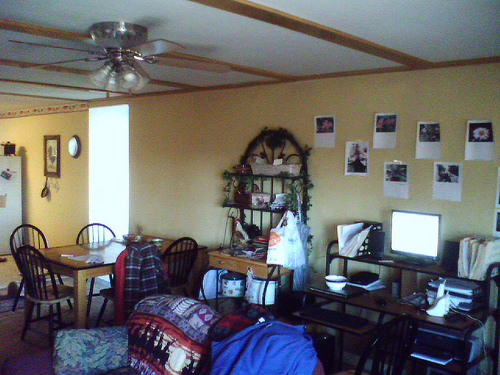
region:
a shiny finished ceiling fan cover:
[83, 21, 146, 48]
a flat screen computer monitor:
[387, 210, 446, 263]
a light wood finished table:
[35, 232, 212, 329]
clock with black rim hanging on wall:
[65, 136, 81, 156]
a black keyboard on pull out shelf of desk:
[297, 301, 372, 331]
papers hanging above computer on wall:
[312, 106, 499, 211]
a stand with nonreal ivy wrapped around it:
[210, 97, 310, 322]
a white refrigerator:
[3, 157, 23, 254]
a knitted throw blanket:
[124, 297, 211, 371]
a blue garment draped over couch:
[207, 318, 321, 374]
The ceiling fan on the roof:
[6, 20, 235, 104]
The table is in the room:
[5, 218, 216, 348]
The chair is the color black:
[8, 235, 72, 351]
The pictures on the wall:
[295, 103, 492, 207]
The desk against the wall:
[293, 224, 498, 371]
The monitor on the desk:
[383, 204, 445, 269]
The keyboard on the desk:
[295, 298, 376, 336]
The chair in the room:
[40, 290, 327, 372]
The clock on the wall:
[62, 130, 84, 159]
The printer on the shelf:
[412, 323, 487, 370]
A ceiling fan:
[7, 18, 234, 114]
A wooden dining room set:
[5, 213, 212, 336]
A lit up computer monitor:
[387, 206, 447, 268]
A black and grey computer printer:
[402, 314, 465, 367]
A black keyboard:
[297, 295, 367, 338]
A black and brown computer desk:
[286, 225, 491, 373]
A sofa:
[35, 292, 330, 372]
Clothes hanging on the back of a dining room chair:
[97, 240, 175, 335]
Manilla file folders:
[451, 235, 497, 290]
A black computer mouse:
[367, 287, 390, 314]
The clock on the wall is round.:
[63, 130, 80, 158]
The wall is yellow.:
[146, 137, 196, 194]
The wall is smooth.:
[141, 119, 201, 193]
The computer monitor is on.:
[388, 205, 442, 266]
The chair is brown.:
[6, 246, 71, 347]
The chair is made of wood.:
[10, 244, 80, 341]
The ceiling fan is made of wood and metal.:
[18, 18, 247, 100]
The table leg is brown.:
[67, 270, 95, 327]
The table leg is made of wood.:
[68, 273, 95, 328]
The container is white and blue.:
[247, 274, 278, 305]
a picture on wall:
[313, 116, 341, 150]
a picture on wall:
[341, 143, 380, 186]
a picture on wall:
[374, 111, 406, 149]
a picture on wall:
[418, 110, 443, 150]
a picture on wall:
[463, 123, 492, 153]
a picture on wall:
[382, 163, 407, 193]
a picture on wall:
[436, 164, 461, 203]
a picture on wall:
[34, 146, 70, 171]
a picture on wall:
[491, 208, 498, 229]